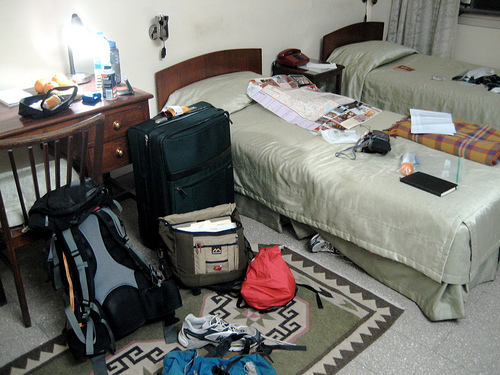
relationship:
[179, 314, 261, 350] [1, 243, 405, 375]
sneaker on top of rug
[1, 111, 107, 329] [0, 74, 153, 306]
chair under desk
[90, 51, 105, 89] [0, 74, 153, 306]
bottle on desk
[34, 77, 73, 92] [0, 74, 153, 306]
oranges on desk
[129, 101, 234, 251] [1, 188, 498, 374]
luggage on top of ground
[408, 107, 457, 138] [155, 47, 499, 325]
papers on top of bed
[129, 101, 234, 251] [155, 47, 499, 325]
luggage near bed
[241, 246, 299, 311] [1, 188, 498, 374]
bag on ground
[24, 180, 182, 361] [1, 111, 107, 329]
hiking pack leaning on chair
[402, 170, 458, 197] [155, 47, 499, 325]
book laying in bed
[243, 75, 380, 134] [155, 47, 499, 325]
map on top of bed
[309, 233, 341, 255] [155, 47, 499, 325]
sneaker under bed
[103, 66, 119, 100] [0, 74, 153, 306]
shaving cream on desk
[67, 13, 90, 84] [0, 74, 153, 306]
lamp on top of desk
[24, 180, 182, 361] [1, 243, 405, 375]
hiking pack on top of rug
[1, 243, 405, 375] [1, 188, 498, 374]
rug on top of ground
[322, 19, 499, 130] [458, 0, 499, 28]
bed near window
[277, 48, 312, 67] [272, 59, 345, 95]
phone on a nightstand